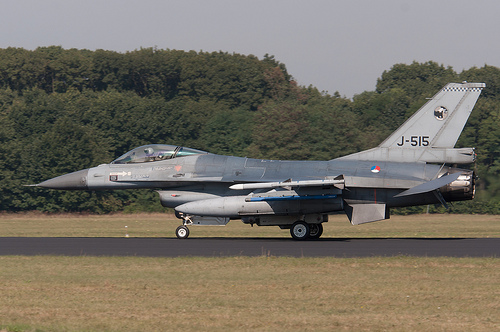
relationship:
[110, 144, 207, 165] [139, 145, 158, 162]
cockpit with pilot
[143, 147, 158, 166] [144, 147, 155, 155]
pilot with helmet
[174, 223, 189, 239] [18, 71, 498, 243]
front wheel of plane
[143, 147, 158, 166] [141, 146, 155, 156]
pilot wearing helmet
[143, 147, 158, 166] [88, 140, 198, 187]
pilot sitting in cockpit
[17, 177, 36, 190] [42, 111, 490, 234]
front of plane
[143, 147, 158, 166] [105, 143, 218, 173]
pilot in cockpit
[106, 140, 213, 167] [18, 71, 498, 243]
top of plane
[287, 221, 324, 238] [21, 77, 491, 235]
rear wheels of plane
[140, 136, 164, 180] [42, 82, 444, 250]
pilot in plane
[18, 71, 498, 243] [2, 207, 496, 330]
plane on ground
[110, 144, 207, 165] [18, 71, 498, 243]
cockpit of a plane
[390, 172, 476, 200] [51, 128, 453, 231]
fins of a plane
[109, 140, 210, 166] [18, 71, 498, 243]
cockpit belonging to plane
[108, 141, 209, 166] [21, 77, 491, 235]
part belonging to plane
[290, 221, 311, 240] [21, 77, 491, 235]
rear wheels belonging to plane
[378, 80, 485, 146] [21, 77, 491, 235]
part belonging to plane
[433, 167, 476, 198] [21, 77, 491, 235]
part belonging to plane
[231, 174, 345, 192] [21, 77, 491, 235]
part belonging to plane